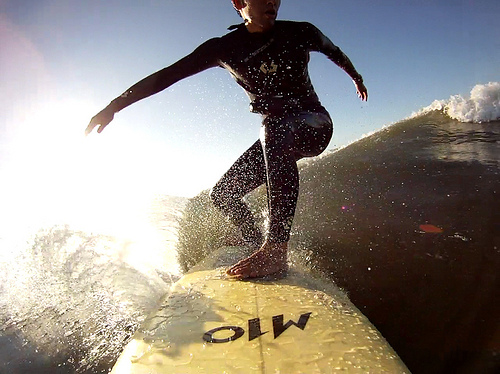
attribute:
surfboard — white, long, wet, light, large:
[106, 202, 406, 372]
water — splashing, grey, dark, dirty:
[1, 88, 499, 371]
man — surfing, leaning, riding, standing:
[76, 3, 380, 285]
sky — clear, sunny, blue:
[2, 3, 498, 237]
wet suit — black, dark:
[112, 20, 361, 242]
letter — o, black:
[168, 313, 247, 364]